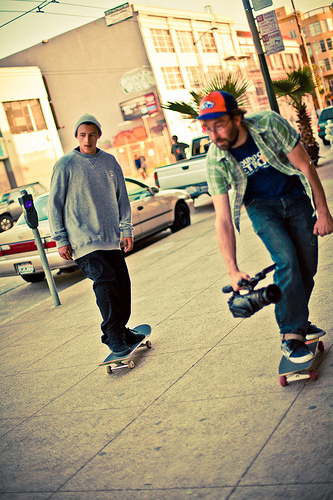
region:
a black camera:
[221, 275, 282, 322]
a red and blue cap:
[185, 88, 254, 125]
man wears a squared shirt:
[184, 87, 331, 292]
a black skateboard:
[270, 334, 326, 392]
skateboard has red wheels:
[273, 340, 327, 386]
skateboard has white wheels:
[88, 318, 157, 377]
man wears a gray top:
[44, 111, 151, 365]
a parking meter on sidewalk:
[14, 186, 72, 315]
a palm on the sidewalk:
[260, 62, 329, 173]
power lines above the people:
[4, 0, 319, 47]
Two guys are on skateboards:
[46, 85, 331, 392]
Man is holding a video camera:
[195, 85, 326, 321]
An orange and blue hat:
[188, 89, 247, 128]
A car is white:
[0, 173, 197, 283]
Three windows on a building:
[146, 22, 221, 57]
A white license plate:
[11, 256, 36, 276]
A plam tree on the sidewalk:
[267, 65, 325, 170]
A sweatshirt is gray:
[45, 148, 137, 262]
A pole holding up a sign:
[240, 7, 282, 116]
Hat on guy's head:
[70, 112, 106, 154]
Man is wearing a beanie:
[57, 104, 116, 163]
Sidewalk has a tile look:
[141, 409, 247, 496]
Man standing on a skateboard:
[99, 301, 174, 394]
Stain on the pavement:
[89, 437, 120, 481]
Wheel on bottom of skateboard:
[122, 356, 140, 375]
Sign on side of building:
[98, 1, 146, 36]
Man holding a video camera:
[213, 229, 299, 324]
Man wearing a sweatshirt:
[39, 148, 176, 265]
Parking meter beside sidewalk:
[15, 181, 74, 290]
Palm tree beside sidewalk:
[263, 46, 324, 117]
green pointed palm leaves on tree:
[166, 66, 275, 89]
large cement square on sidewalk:
[62, 382, 264, 490]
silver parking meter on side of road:
[11, 187, 50, 237]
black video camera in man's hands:
[197, 248, 289, 323]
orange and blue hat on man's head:
[182, 87, 243, 130]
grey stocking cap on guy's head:
[62, 105, 110, 134]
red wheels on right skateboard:
[263, 363, 320, 390]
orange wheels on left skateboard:
[95, 359, 146, 380]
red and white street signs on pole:
[240, 11, 294, 61]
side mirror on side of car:
[144, 184, 176, 202]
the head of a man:
[203, 84, 253, 156]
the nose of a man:
[194, 130, 226, 167]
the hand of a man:
[217, 263, 268, 299]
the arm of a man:
[208, 150, 236, 280]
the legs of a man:
[85, 214, 182, 367]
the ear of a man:
[223, 92, 263, 134]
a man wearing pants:
[258, 188, 329, 364]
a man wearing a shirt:
[193, 170, 283, 282]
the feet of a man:
[266, 314, 323, 389]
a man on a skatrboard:
[155, 103, 323, 408]